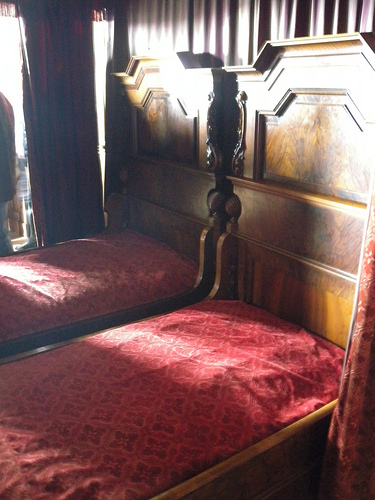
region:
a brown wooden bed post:
[221, 190, 248, 229]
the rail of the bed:
[145, 393, 339, 498]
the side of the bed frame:
[150, 393, 340, 498]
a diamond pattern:
[202, 322, 230, 339]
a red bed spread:
[0, 294, 360, 498]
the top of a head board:
[220, 32, 373, 79]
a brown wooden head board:
[205, 27, 373, 297]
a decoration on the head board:
[228, 87, 248, 178]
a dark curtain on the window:
[16, 2, 104, 249]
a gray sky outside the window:
[0, 16, 21, 91]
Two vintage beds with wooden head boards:
[12, 7, 360, 427]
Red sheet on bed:
[69, 307, 326, 462]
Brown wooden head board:
[223, 31, 373, 241]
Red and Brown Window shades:
[4, 15, 99, 232]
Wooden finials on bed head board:
[189, 165, 253, 312]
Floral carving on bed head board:
[222, 76, 279, 203]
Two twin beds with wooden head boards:
[23, 15, 367, 498]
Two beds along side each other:
[9, 15, 363, 454]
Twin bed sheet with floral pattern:
[65, 349, 200, 466]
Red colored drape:
[320, 343, 368, 491]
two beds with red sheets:
[3, 150, 364, 496]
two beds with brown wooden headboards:
[1, 145, 347, 498]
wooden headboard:
[218, 38, 362, 300]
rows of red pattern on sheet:
[2, 354, 266, 442]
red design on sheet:
[148, 410, 186, 437]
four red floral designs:
[122, 390, 188, 437]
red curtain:
[31, 1, 95, 242]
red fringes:
[1, 3, 25, 17]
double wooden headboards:
[109, 32, 370, 236]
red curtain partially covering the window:
[1, 3, 108, 243]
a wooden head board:
[102, 45, 230, 264]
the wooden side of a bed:
[156, 395, 342, 498]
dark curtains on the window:
[12, 4, 114, 248]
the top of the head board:
[223, 34, 374, 82]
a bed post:
[226, 191, 242, 226]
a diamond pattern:
[153, 391, 188, 415]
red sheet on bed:
[88, 350, 191, 457]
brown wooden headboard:
[255, 115, 353, 284]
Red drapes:
[324, 362, 369, 495]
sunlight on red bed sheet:
[0, 256, 63, 297]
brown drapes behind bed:
[131, 7, 373, 34]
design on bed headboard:
[199, 84, 219, 175]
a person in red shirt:
[0, 87, 17, 260]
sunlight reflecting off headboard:
[105, 41, 205, 143]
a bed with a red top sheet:
[10, 332, 338, 498]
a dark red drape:
[18, 0, 104, 227]